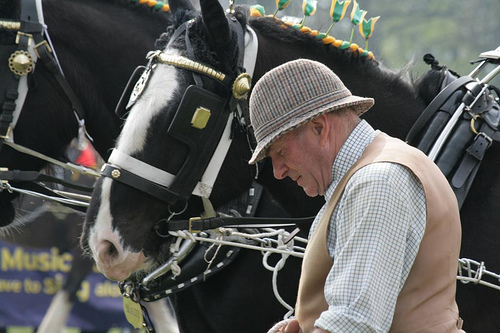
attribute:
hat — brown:
[229, 54, 394, 169]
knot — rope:
[251, 227, 305, 280]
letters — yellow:
[16, 243, 87, 287]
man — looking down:
[214, 47, 424, 236]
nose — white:
[79, 232, 124, 267]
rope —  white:
[142, 216, 499, 321]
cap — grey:
[248, 57, 374, 158]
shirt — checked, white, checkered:
[309, 118, 424, 331]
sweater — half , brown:
[286, 147, 463, 331]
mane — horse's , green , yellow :
[269, 0, 411, 63]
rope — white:
[188, 224, 498, 299]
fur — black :
[85, 73, 266, 287]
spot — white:
[136, 99, 155, 115]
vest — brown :
[288, 134, 460, 328]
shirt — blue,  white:
[300, 117, 453, 327]